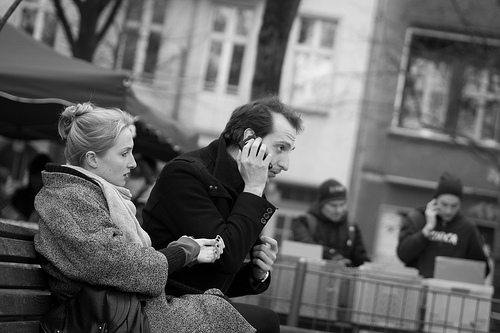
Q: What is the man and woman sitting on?
A: A bench.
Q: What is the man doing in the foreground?
A: Talking on a cell phone.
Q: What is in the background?
A: Buildings.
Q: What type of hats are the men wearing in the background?
A: Beanies.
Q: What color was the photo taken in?
A: Black and white.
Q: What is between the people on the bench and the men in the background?
A: A fence.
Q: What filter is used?
A: Black and white.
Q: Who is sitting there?
A: Couple.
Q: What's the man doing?
A: Talking on phone.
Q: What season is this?
A: Winter.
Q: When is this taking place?
A: Daytime.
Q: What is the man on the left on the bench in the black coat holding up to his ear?
A: Cellular phone.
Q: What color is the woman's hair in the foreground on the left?
A: Blonde.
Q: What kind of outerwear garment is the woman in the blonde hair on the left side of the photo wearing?
A: Coat.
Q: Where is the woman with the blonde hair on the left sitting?
A: Bench.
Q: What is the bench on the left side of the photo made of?
A: Wood.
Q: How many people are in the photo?
A: Four.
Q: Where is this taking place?
A: In the park.